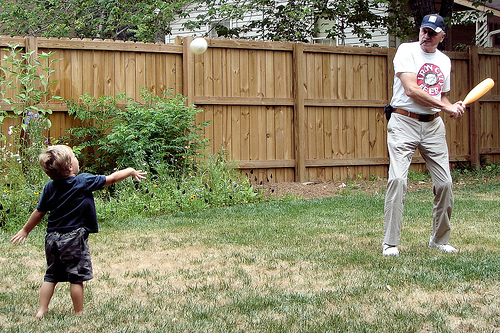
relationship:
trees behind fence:
[2, 1, 416, 38] [0, 30, 389, 165]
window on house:
[310, 5, 345, 44] [154, 3, 399, 42]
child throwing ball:
[5, 135, 153, 321] [183, 32, 212, 60]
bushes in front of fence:
[93, 89, 261, 214] [0, 30, 389, 165]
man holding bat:
[371, 7, 494, 260] [459, 73, 497, 110]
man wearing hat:
[371, 7, 494, 260] [420, 10, 448, 38]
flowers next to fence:
[146, 139, 218, 205] [0, 30, 389, 165]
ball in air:
[183, 32, 212, 60] [111, 4, 282, 98]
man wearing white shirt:
[371, 7, 494, 260] [386, 41, 453, 117]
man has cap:
[371, 7, 494, 260] [420, 10, 448, 38]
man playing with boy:
[371, 7, 494, 260] [5, 135, 153, 321]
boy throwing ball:
[5, 135, 153, 321] [183, 32, 212, 60]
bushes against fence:
[93, 89, 261, 214] [0, 30, 389, 165]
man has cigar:
[371, 7, 494, 260] [416, 37, 428, 48]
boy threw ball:
[5, 135, 153, 321] [183, 32, 212, 60]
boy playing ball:
[5, 135, 153, 321] [187, 37, 208, 55]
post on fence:
[289, 41, 313, 186] [0, 30, 389, 165]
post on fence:
[179, 31, 204, 119] [0, 30, 389, 165]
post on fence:
[20, 34, 46, 134] [0, 30, 389, 165]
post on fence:
[468, 39, 485, 168] [0, 30, 389, 165]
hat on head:
[420, 10, 448, 38] [410, 9, 453, 57]